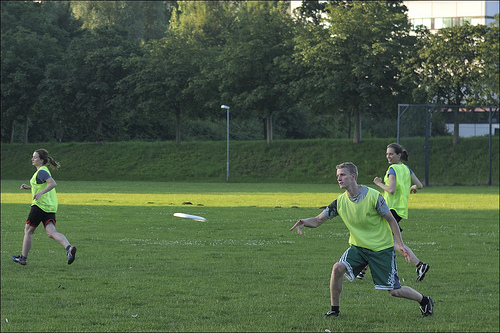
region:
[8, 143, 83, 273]
A girl running on the grass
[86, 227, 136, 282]
Part of the green grass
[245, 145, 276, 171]
Part of the green bushes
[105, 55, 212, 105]
Part of the green trees in distance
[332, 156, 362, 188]
The head of the person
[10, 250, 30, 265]
The left foot of the person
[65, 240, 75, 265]
The right foot of the person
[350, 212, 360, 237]
Part of the green shirt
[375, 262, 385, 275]
Part of the green shorts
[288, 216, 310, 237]
The right hand of the person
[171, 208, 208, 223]
a flying white frisbee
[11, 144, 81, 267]
a young girl running on a field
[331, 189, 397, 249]
a bright green shirt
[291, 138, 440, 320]
a pair of people playing frisbee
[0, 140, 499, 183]
a long row of bushes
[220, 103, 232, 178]
a small light pole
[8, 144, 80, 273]
a girl in a bright green vest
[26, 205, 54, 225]
a pair of black and red shorts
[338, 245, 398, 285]
a pair of dark green shorts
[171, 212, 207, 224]
a flying frisbee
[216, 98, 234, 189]
a street light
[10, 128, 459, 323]
young people playing Frisbee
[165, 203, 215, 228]
Frisbee in the air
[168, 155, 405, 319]
boy throwing a frisbee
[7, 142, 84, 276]
woman combs in a pony tail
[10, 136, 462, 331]
players wear green vest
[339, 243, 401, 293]
green shorts with white stripes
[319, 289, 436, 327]
a pair of black shoes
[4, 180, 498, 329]
field is cover with grass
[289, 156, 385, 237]
boy is blonde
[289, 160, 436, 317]
player throws frisbee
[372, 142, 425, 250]
player smiles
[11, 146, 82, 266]
player runs down field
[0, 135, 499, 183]
hedgerow lines the field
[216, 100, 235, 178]
light post is turned off in the background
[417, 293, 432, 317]
sneaker worn by player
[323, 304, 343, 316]
sneaker worn by player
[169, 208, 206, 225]
frisbee flies through the air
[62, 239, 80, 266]
sneaker worn by player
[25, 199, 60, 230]
shorts worn by player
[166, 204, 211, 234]
Frisbee in the sky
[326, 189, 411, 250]
man wearing a green shirt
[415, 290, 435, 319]
man wearing black shoes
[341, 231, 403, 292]
man wearing green shorts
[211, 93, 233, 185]
lamp post in the park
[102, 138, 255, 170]
hedges in the park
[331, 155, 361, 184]
man with blond hair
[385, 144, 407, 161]
woman with brown hair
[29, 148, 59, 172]
woman with a ponytail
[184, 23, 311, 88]
leaves on a tree